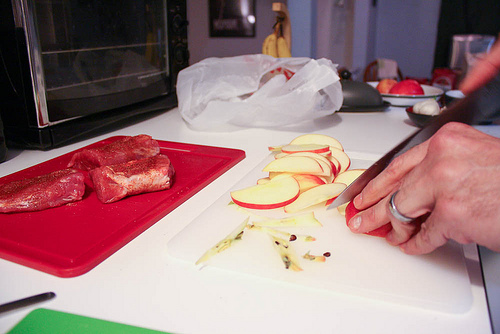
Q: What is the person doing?
A: Cutting an apple.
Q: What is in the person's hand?
A: A knife.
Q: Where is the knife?
A: In the person's hand.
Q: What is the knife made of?
A: Metal.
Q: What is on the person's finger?
A: A ring.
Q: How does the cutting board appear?
A: White in color.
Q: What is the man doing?
A: Slicing the apples.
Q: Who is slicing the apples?
A: A man.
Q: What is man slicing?
A: Apples.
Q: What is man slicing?
A: The apples.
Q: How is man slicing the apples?
A: Knife.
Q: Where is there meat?
A: On the red tray.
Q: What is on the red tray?
A: Meat.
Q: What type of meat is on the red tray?
A: Beef.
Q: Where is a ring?
A: Around a finger.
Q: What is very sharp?
A: Knife.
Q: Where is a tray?
A: On countertop.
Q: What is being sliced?
A: An apple.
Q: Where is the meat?
A: On red board.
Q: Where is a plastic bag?
A: On the table.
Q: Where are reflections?
A: On microwave window.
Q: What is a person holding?
A: A knife.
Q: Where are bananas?
A: On other side of the table.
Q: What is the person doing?
A: Cutting food.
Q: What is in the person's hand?
A: A knife.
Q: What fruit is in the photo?
A: A apple.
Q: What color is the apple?
A: Red.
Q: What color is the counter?
A: White.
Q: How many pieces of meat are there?
A: Three.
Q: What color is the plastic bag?
A: White.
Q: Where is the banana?
A: On the hook.